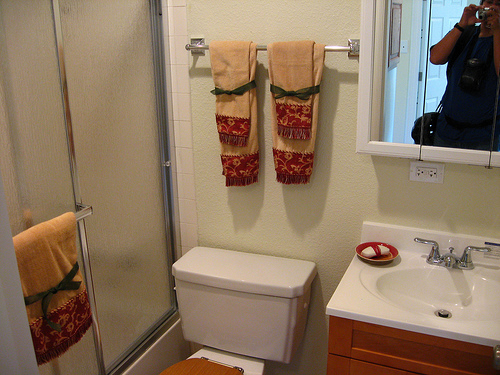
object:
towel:
[210, 39, 262, 187]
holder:
[185, 37, 361, 56]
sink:
[168, 245, 316, 364]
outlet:
[409, 161, 444, 182]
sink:
[371, 258, 500, 323]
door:
[52, 0, 182, 375]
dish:
[355, 240, 403, 265]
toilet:
[152, 244, 316, 375]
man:
[409, 0, 499, 152]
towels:
[206, 38, 324, 188]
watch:
[451, 20, 469, 36]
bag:
[411, 88, 446, 145]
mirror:
[376, 0, 499, 154]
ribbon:
[210, 79, 258, 96]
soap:
[354, 242, 394, 259]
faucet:
[413, 236, 491, 269]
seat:
[156, 344, 265, 375]